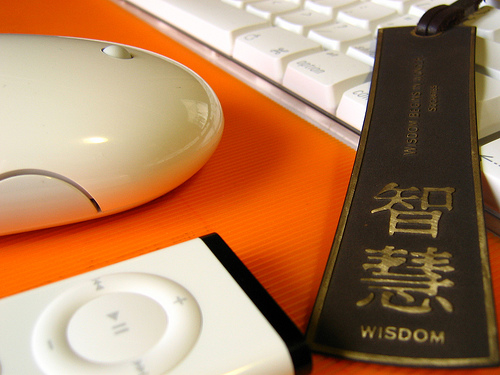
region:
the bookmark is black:
[335, 31, 496, 360]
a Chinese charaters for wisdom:
[368, 183, 456, 374]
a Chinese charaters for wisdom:
[327, 140, 478, 357]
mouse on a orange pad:
[26, 28, 222, 193]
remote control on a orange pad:
[27, 269, 244, 374]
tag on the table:
[358, 15, 493, 370]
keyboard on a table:
[221, 13, 469, 125]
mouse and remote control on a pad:
[1, 16, 253, 368]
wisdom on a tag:
[338, 309, 452, 357]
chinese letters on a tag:
[361, 170, 467, 326]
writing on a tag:
[395, 45, 455, 172]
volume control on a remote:
[63, 286, 178, 353]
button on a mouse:
[13, 165, 110, 228]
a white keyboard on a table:
[130, 4, 499, 239]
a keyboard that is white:
[112, 7, 497, 224]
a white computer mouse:
[8, 16, 379, 348]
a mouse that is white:
[15, 2, 301, 316]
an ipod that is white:
[27, 215, 358, 374]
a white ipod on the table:
[62, 168, 352, 374]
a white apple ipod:
[48, 194, 333, 372]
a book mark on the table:
[276, 7, 483, 287]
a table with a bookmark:
[289, 14, 486, 246]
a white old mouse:
[49, 11, 309, 264]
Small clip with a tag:
[303, 0, 498, 370]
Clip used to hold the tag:
[415, 0, 484, 32]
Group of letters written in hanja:
[354, 178, 459, 317]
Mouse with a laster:
[0, 30, 227, 235]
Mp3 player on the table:
[0, 233, 308, 371]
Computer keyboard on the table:
[123, 0, 499, 229]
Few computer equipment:
[1, 0, 498, 374]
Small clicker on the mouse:
[104, 40, 136, 62]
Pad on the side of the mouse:
[4, 170, 99, 235]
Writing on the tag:
[359, 53, 459, 350]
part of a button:
[176, 298, 193, 335]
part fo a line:
[263, 290, 288, 322]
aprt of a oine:
[273, 213, 316, 279]